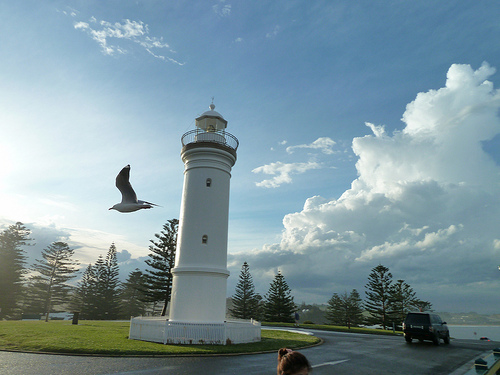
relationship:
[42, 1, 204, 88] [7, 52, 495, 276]
clouds in sky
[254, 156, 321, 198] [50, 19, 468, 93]
cloud in sky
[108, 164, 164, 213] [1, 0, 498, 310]
bird in sky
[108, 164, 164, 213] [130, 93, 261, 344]
bird by statue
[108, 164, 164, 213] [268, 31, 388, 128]
bird in sky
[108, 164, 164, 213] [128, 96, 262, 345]
bird by building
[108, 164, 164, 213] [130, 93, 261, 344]
bird near a statue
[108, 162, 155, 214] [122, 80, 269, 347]
bird near a statue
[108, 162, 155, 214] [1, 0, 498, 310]
bird in sky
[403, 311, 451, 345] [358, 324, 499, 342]
car parked by lake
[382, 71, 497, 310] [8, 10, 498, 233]
clouds in sky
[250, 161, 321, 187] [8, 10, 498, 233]
cloud in sky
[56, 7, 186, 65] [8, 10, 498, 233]
clouds in sky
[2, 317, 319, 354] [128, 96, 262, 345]
grass at base of building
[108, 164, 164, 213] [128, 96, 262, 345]
bird flying by building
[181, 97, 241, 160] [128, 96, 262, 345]
top section of building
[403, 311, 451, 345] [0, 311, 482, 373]
car parked in parking lot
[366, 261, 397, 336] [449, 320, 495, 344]
tree in front of water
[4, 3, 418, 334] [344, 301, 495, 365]
day within lake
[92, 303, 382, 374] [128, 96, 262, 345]
round about next to building